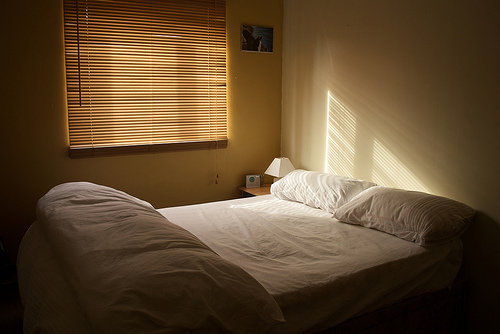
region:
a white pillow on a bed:
[332, 184, 480, 249]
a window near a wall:
[63, 9, 233, 160]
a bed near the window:
[7, 165, 483, 326]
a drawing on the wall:
[238, 19, 277, 57]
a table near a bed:
[233, 177, 293, 201]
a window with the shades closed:
[63, 11, 238, 163]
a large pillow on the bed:
[30, 166, 287, 333]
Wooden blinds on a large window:
[20, 0, 240, 171]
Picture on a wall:
[231, 10, 291, 80]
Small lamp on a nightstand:
[230, 145, 295, 201]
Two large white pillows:
[265, 160, 490, 245]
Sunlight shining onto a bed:
[105, 65, 490, 301]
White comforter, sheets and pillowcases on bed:
[2, 166, 483, 330]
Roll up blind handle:
[48, 2, 110, 134]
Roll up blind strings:
[176, 0, 230, 196]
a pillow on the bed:
[348, 192, 441, 226]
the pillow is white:
[360, 191, 420, 226]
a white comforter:
[105, 217, 165, 272]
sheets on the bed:
[205, 215, 275, 244]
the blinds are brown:
[116, 53, 189, 123]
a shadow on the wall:
[322, 121, 374, 165]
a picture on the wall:
[241, 27, 272, 52]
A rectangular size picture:
[237, 19, 277, 55]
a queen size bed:
[30, 168, 469, 305]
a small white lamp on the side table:
[261, 154, 294, 185]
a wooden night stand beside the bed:
[235, 180, 280, 202]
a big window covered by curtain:
[52, 2, 234, 157]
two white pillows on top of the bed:
[267, 167, 482, 262]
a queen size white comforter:
[10, 180, 273, 332]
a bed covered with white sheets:
[39, 177, 477, 311]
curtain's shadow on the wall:
[313, 83, 435, 229]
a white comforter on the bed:
[5, 182, 287, 331]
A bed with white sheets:
[20, 193, 465, 332]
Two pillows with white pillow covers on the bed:
[270, 168, 478, 247]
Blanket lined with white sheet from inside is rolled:
[38, 181, 281, 332]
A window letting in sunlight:
[60, 2, 229, 151]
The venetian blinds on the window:
[69, 3, 224, 144]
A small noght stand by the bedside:
[243, 184, 271, 194]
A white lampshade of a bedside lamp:
[265, 156, 295, 176]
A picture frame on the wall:
[240, 22, 275, 52]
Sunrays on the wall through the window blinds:
[326, 90, 428, 193]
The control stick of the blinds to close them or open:
[77, 4, 80, 108]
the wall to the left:
[2, 26, 292, 235]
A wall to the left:
[3, 25, 293, 239]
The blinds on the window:
[45, 25, 251, 156]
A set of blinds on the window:
[38, 25, 246, 172]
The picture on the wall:
[234, 22, 288, 69]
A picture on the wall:
[234, 26, 281, 61]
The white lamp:
[262, 153, 301, 187]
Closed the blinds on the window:
[52, 0, 235, 155]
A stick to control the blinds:
[72, 4, 90, 113]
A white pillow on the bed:
[271, 166, 371, 212]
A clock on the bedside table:
[239, 166, 263, 191]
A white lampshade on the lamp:
[262, 154, 299, 179]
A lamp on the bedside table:
[262, 151, 294, 186]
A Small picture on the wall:
[234, 14, 281, 59]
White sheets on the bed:
[232, 199, 346, 271]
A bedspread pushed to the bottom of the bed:
[29, 177, 175, 319]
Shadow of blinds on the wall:
[319, 86, 392, 168]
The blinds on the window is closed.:
[58, 10, 230, 146]